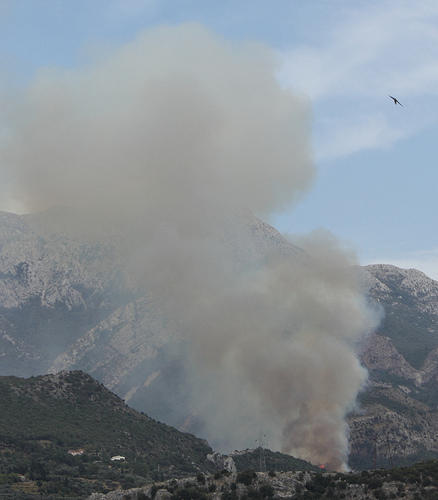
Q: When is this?
A: Daytime.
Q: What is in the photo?
A: Mountain.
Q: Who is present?
A: No one.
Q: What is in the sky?
A: Clouds.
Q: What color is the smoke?
A: Gray.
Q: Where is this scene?
A: At a fire.